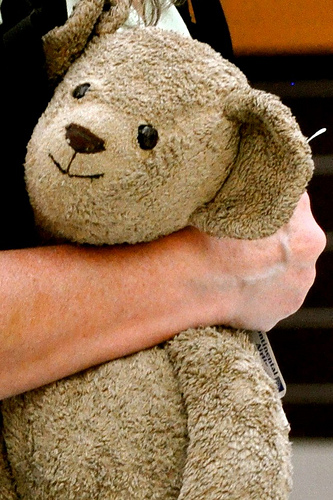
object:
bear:
[0, 0, 316, 498]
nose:
[63, 117, 106, 157]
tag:
[248, 328, 286, 401]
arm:
[0, 218, 196, 410]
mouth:
[47, 147, 105, 189]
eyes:
[71, 77, 159, 152]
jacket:
[0, 0, 238, 231]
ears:
[34, 1, 316, 245]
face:
[22, 32, 227, 245]